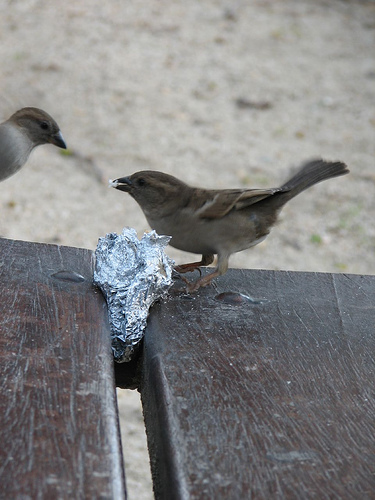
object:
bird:
[109, 159, 350, 295]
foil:
[108, 180, 127, 188]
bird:
[0, 107, 67, 180]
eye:
[138, 178, 147, 186]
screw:
[47, 270, 85, 283]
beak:
[113, 176, 133, 191]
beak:
[52, 129, 66, 149]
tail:
[280, 159, 350, 205]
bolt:
[214, 292, 241, 302]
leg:
[199, 252, 228, 287]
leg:
[201, 253, 213, 267]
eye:
[40, 122, 48, 129]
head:
[112, 170, 192, 218]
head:
[7, 107, 66, 149]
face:
[35, 117, 53, 140]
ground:
[0, 0, 375, 500]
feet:
[171, 262, 222, 294]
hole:
[113, 335, 181, 500]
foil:
[92, 226, 175, 363]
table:
[0, 238, 375, 498]